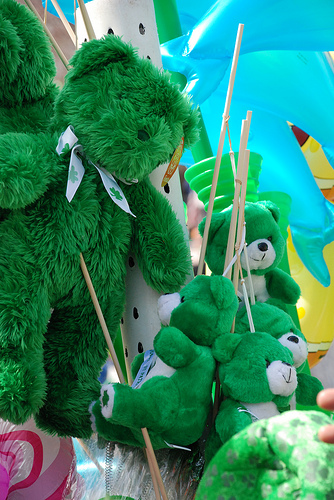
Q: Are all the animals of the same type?
A: Yes, all the animals are bears.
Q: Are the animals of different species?
A: No, all the animals are bears.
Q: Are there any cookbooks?
A: No, there are no cookbooks.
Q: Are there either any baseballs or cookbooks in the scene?
A: No, there are no cookbooks or baseballs.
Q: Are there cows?
A: No, there are no cows.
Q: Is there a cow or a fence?
A: No, there are no cows or fences.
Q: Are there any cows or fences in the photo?
A: No, there are no cows or fences.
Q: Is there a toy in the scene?
A: Yes, there is a toy.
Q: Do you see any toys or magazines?
A: Yes, there is a toy.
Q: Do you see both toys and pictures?
A: No, there is a toy but no pictures.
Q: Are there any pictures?
A: No, there are no pictures.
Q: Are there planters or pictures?
A: No, there are no pictures or planters.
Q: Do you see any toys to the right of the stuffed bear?
A: Yes, there is a toy to the right of the stuffed bear.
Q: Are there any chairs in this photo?
A: No, there are no chairs.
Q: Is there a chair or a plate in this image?
A: No, there are no chairs or plates.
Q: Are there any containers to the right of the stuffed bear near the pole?
A: Yes, there is a container to the right of the stuffed bear.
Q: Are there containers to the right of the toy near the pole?
A: Yes, there is a container to the right of the stuffed bear.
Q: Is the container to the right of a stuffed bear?
A: Yes, the container is to the right of a stuffed bear.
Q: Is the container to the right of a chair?
A: No, the container is to the right of a stuffed bear.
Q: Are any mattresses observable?
A: No, there are no mattresses.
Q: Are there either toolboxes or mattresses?
A: No, there are no mattresses or toolboxes.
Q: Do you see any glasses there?
A: No, there are no glasses.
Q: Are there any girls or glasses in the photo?
A: No, there are no glasses or girls.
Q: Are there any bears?
A: Yes, there is a bear.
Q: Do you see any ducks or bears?
A: Yes, there is a bear.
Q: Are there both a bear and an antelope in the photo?
A: No, there is a bear but no antelopes.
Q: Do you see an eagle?
A: No, there are no eagles.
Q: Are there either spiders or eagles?
A: No, there are no eagles or spiders.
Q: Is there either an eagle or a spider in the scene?
A: No, there are no eagles or spiders.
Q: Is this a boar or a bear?
A: This is a bear.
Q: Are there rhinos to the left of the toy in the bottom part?
A: No, there is a bear to the left of the toy.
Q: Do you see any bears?
A: Yes, there are bears.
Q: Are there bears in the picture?
A: Yes, there are bears.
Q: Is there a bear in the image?
A: Yes, there are bears.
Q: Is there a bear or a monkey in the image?
A: Yes, there are bears.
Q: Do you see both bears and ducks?
A: No, there are bears but no ducks.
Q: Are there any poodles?
A: No, there are no poodles.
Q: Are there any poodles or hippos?
A: No, there are no poodles or hippos.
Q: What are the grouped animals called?
A: The animals are bears.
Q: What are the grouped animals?
A: The animals are bears.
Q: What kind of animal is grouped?
A: The animal is bears.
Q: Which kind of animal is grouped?
A: The animal is bears.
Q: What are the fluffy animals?
A: The animals are bears.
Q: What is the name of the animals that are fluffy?
A: The animals are bears.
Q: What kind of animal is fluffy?
A: The animal is bears.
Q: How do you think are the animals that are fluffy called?
A: The animals are bears.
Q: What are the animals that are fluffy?
A: The animals are bears.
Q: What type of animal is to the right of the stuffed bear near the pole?
A: The animals are bears.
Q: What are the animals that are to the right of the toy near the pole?
A: The animals are bears.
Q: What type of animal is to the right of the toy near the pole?
A: The animals are bears.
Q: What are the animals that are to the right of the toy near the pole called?
A: The animals are bears.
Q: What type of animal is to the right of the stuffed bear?
A: The animals are bears.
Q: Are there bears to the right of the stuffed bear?
A: Yes, there are bears to the right of the stuffed bear.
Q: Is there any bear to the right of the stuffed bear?
A: Yes, there are bears to the right of the stuffed bear.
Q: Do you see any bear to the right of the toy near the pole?
A: Yes, there are bears to the right of the stuffed bear.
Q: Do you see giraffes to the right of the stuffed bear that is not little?
A: No, there are bears to the right of the stuffed bear.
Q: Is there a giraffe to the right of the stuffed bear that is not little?
A: No, there are bears to the right of the stuffed bear.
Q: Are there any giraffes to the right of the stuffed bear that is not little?
A: No, there are bears to the right of the stuffed bear.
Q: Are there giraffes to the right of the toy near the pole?
A: No, there are bears to the right of the stuffed bear.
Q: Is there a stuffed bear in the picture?
A: Yes, there is a stuffed bear.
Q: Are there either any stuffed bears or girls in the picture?
A: Yes, there is a stuffed bear.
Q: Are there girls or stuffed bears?
A: Yes, there is a stuffed bear.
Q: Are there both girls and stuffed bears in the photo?
A: No, there is a stuffed bear but no girls.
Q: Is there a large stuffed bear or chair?
A: Yes, there is a large stuffed bear.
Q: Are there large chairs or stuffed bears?
A: Yes, there is a large stuffed bear.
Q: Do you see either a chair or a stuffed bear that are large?
A: Yes, the stuffed bear is large.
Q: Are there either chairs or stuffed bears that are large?
A: Yes, the stuffed bear is large.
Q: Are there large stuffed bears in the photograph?
A: Yes, there is a large stuffed bear.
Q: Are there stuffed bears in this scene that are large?
A: Yes, there is a stuffed bear that is large.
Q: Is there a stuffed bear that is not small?
A: Yes, there is a large stuffed bear.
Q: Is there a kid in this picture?
A: No, there are no children.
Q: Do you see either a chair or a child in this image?
A: No, there are no children or chairs.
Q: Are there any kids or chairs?
A: No, there are no kids or chairs.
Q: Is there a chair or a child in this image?
A: No, there are no children or chairs.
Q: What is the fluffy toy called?
A: The toy is a stuffed bear.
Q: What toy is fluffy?
A: The toy is a stuffed bear.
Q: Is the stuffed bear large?
A: Yes, the stuffed bear is large.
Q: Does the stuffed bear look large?
A: Yes, the stuffed bear is large.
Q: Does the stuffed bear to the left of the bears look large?
A: Yes, the stuffed bear is large.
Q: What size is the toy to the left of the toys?
A: The stuffed bear is large.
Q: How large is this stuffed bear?
A: The stuffed bear is large.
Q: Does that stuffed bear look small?
A: No, the stuffed bear is large.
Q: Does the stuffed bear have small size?
A: No, the stuffed bear is large.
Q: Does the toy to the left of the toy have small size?
A: No, the stuffed bear is large.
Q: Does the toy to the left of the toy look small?
A: No, the stuffed bear is large.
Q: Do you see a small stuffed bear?
A: No, there is a stuffed bear but it is large.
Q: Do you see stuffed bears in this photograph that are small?
A: No, there is a stuffed bear but it is large.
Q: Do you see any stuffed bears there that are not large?
A: No, there is a stuffed bear but it is large.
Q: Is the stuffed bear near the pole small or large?
A: The stuffed bear is large.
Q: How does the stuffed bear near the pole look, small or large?
A: The stuffed bear is large.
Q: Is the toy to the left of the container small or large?
A: The stuffed bear is large.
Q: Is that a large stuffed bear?
A: Yes, that is a large stuffed bear.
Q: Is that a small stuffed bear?
A: No, that is a large stuffed bear.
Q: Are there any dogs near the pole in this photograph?
A: No, there is a stuffed bear near the pole.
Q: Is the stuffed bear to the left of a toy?
A: Yes, the stuffed bear is to the left of a toy.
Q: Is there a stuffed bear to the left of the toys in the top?
A: Yes, there is a stuffed bear to the left of the toys.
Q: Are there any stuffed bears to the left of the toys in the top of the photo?
A: Yes, there is a stuffed bear to the left of the toys.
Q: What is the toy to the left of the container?
A: The toy is a stuffed bear.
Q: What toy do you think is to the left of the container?
A: The toy is a stuffed bear.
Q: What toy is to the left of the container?
A: The toy is a stuffed bear.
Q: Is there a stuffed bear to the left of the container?
A: Yes, there is a stuffed bear to the left of the container.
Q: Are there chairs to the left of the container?
A: No, there is a stuffed bear to the left of the container.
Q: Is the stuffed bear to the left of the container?
A: Yes, the stuffed bear is to the left of the container.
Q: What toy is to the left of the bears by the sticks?
A: The toy is a stuffed bear.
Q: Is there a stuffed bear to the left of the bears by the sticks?
A: Yes, there is a stuffed bear to the left of the bears.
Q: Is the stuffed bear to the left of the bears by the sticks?
A: Yes, the stuffed bear is to the left of the bears.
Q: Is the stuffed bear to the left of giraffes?
A: No, the stuffed bear is to the left of the bears.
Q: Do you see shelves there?
A: No, there are no shelves.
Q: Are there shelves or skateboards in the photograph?
A: No, there are no shelves or skateboards.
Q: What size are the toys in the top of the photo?
A: The toys are large.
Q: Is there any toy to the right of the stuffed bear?
A: Yes, there are toys to the right of the stuffed bear.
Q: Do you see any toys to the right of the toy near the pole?
A: Yes, there are toys to the right of the stuffed bear.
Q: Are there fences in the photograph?
A: No, there are no fences.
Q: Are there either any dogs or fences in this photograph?
A: No, there are no fences or dogs.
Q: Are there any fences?
A: No, there are no fences.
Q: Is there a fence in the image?
A: No, there are no fences.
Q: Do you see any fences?
A: No, there are no fences.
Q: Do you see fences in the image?
A: No, there are no fences.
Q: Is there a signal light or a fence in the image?
A: No, there are no fences or traffic lights.